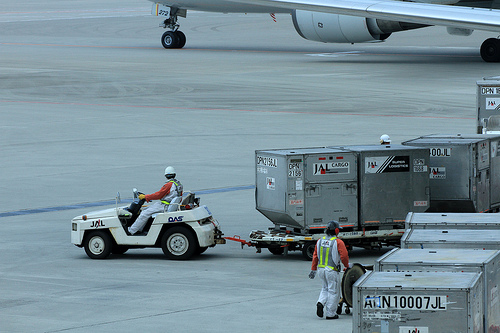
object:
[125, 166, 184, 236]
man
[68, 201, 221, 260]
white truck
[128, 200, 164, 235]
white pants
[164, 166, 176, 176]
hat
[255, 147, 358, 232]
containers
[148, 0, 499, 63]
plane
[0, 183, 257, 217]
line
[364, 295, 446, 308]
number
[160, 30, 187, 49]
wheels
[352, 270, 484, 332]
silver tank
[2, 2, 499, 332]
road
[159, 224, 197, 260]
wheel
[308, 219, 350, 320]
man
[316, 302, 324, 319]
shoes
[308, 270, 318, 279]
hand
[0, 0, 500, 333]
airport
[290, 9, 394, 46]
engine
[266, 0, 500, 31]
wing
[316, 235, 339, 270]
vest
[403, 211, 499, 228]
luggage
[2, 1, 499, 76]
cement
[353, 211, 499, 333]
boxes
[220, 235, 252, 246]
hook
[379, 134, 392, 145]
person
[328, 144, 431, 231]
canister